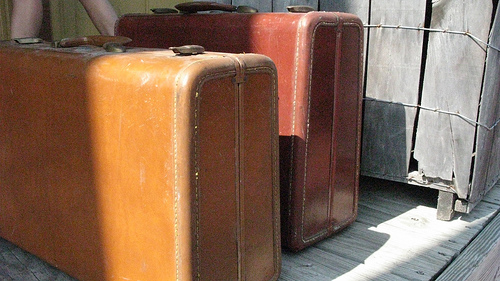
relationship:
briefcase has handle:
[5, 34, 284, 277] [45, 31, 132, 57]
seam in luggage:
[224, 55, 257, 277] [4, 34, 284, 276]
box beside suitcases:
[367, 2, 497, 227] [2, 0, 367, 280]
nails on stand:
[410, 235, 461, 275] [226, 146, 498, 281]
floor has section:
[0, 178, 498, 279] [386, 209, 413, 227]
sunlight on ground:
[393, 211, 431, 245] [293, 94, 330, 129]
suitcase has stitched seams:
[0, 8, 365, 277] [188, 86, 207, 279]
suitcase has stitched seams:
[0, 8, 365, 277] [270, 73, 280, 278]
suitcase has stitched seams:
[121, 8, 356, 237] [299, 26, 314, 242]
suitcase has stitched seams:
[121, 8, 356, 237] [353, 28, 359, 215]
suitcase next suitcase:
[0, 8, 365, 277] [265, 3, 377, 240]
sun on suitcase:
[108, 57, 169, 267] [0, 8, 365, 277]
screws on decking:
[437, 250, 445, 256] [280, 181, 498, 278]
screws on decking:
[411, 216, 419, 221] [280, 181, 498, 278]